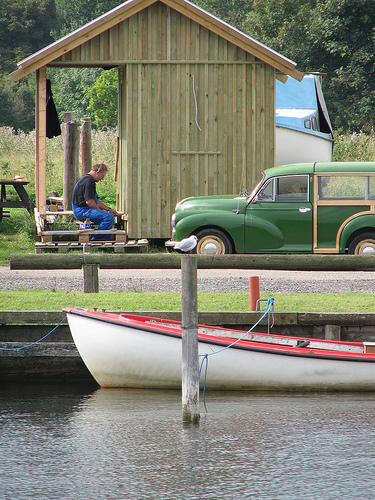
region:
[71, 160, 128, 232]
man sitting on bench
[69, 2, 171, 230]
carpenter working on wooden building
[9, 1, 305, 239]
newly constructed wooden building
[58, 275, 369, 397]
boat docked at the shore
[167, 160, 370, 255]
a green antique truck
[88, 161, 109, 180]
the head of a man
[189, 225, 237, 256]
the front wheel of a truck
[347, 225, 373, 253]
the back wheel of a truck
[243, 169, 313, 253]
the door of a truck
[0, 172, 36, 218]
a wooden picnic table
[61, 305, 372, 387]
Red and white boat in water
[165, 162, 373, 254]
Green vehicle parked on road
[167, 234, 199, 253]
Bird perched on rail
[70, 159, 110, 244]
Man sitting on chair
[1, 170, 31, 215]
Picnic table in the grass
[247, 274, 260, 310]
Orange pole in the ground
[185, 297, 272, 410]
Blue tie hold boat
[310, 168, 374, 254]
Wood detail on vehicle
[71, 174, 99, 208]
Man wearing black shirt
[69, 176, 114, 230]
Man wearing blue overalls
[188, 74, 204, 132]
a white cord on the side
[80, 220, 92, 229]
a bottle with a blue lable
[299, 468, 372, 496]
smooth ripples on the water surface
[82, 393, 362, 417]
a reflection in the water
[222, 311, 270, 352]
a blue tether rope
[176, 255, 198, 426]
a wooden post in the water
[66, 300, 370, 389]
a red and white boat in the water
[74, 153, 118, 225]
a man wearing denim overalls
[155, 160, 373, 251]
an old fashioned green vehicle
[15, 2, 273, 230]
a small wooden shed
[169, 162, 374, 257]
a green and brown car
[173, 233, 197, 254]
a bird is standing on a post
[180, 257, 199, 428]
a thick wooden post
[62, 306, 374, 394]
a boat is in the water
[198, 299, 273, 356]
a blue piece of rope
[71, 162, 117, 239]
a man is sitting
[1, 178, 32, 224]
a dark wooden bench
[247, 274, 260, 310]
a small red post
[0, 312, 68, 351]
a thin blue string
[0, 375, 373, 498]
a calm patch of water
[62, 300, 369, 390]
Boat secured to posts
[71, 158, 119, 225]
Man working on shed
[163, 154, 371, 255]
Old time green car parked by shed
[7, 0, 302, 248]
Wooden shed across from water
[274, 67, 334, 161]
Boat behind the shed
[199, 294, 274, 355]
Rope securing the boat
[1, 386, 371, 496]
Calm expanse of water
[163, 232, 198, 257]
Bird on the fence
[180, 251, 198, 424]
Wooden post sticking out of the water